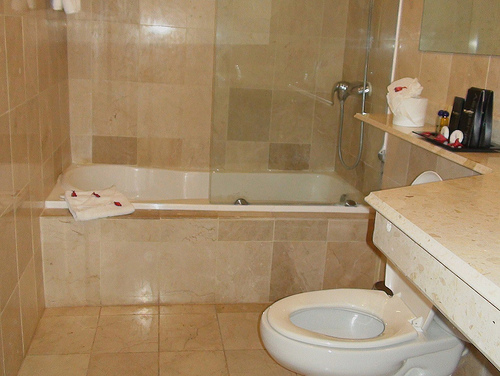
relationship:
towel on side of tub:
[64, 185, 138, 223] [38, 150, 383, 312]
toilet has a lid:
[255, 168, 473, 375] [381, 167, 447, 330]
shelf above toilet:
[350, 104, 499, 175] [255, 168, 473, 375]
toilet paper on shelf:
[384, 72, 428, 134] [350, 104, 499, 175]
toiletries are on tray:
[430, 82, 495, 146] [412, 124, 499, 155]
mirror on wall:
[415, 2, 500, 57] [340, 3, 500, 375]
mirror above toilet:
[415, 2, 500, 57] [255, 168, 473, 375]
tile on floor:
[19, 299, 329, 375] [14, 297, 303, 375]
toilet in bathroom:
[255, 168, 473, 375] [1, 0, 499, 374]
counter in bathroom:
[363, 165, 498, 372] [1, 0, 499, 374]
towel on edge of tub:
[64, 185, 138, 223] [38, 150, 383, 312]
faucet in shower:
[347, 77, 375, 104] [37, 2, 399, 302]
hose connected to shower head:
[329, 1, 380, 169] [326, 75, 355, 108]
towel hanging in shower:
[48, 0, 87, 15] [37, 2, 399, 302]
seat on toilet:
[262, 284, 415, 352] [255, 168, 473, 375]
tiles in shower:
[90, 135, 136, 165] [37, 2, 399, 302]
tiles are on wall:
[63, 1, 348, 171] [64, 1, 367, 177]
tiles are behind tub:
[63, 1, 348, 171] [38, 150, 383, 312]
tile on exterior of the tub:
[41, 207, 392, 310] [41, 207, 391, 311]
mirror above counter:
[415, 2, 500, 57] [350, 104, 499, 175]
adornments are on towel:
[69, 187, 123, 208] [64, 185, 138, 223]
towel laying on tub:
[64, 185, 138, 223] [38, 150, 383, 312]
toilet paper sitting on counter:
[384, 72, 428, 134] [350, 104, 499, 175]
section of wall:
[397, 3, 500, 122] [340, 3, 500, 375]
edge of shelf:
[349, 105, 366, 123] [350, 104, 499, 175]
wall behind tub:
[64, 1, 367, 177] [38, 150, 383, 312]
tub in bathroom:
[38, 150, 383, 312] [1, 0, 499, 374]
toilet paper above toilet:
[384, 72, 428, 134] [255, 168, 473, 375]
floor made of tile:
[14, 297, 303, 375] [19, 299, 329, 375]